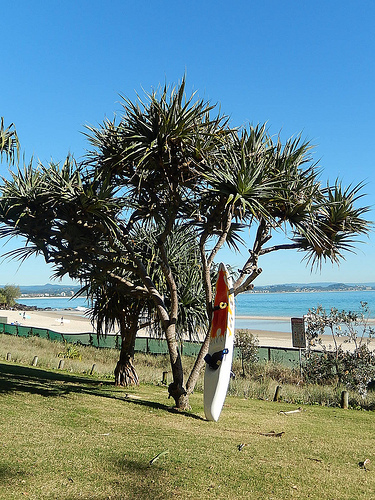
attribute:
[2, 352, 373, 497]
field — grassy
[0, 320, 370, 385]
fence — green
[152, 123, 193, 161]
leaves — green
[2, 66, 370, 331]
leaves — green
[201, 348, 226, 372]
seat — black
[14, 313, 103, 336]
sand — tan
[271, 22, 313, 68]
sky — blue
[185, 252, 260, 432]
kayak — orange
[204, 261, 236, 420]
kayak — red, white